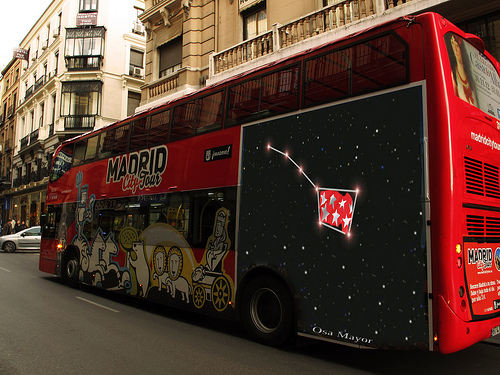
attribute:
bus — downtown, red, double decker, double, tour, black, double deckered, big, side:
[58, 94, 215, 303]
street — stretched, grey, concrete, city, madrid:
[30, 292, 79, 321]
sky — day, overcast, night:
[21, 1, 33, 7]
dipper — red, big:
[254, 137, 352, 233]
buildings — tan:
[42, 7, 237, 60]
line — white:
[92, 303, 109, 310]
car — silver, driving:
[8, 231, 33, 253]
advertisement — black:
[361, 188, 406, 273]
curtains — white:
[51, 14, 64, 29]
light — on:
[454, 242, 464, 254]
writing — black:
[149, 150, 162, 166]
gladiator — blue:
[71, 183, 92, 245]